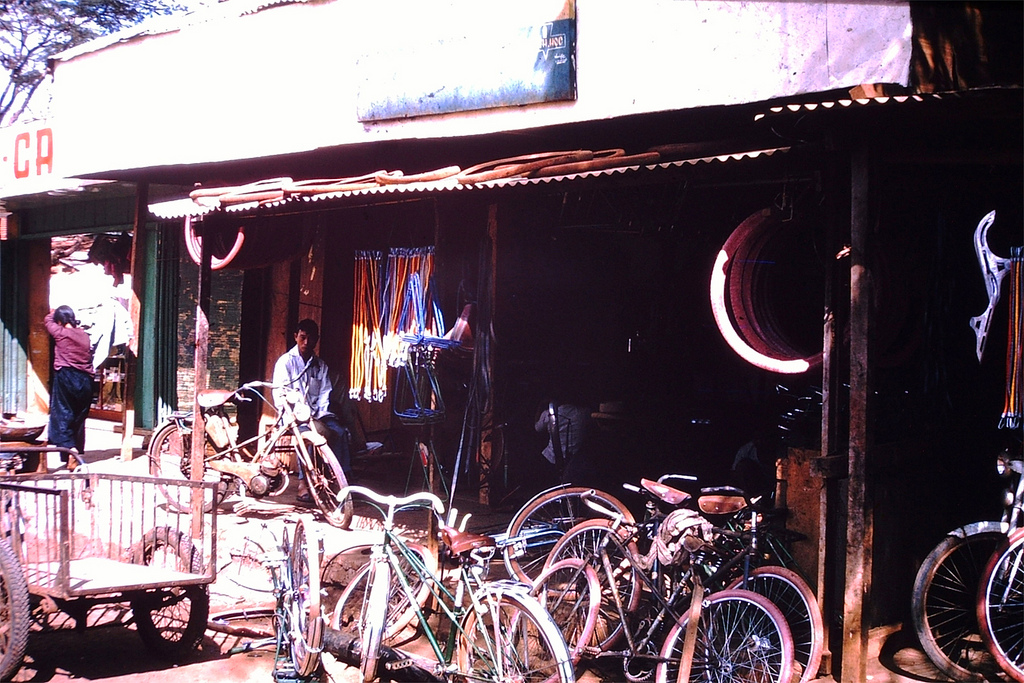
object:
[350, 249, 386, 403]
curtain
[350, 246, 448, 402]
window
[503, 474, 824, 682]
bicycle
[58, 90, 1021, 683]
bike shop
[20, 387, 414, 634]
sidewalk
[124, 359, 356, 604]
sidewalk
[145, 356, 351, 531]
bike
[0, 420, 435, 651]
sidewalk